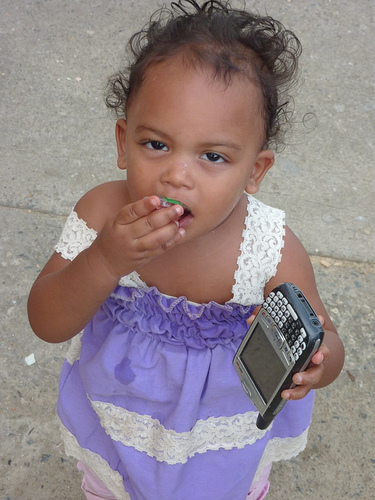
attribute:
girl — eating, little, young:
[23, 1, 349, 500]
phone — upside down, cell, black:
[227, 276, 328, 432]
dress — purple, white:
[48, 187, 320, 496]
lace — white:
[224, 191, 291, 312]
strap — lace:
[48, 200, 149, 299]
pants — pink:
[70, 458, 274, 499]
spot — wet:
[110, 352, 146, 390]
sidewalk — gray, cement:
[3, 2, 372, 500]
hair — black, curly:
[96, 2, 322, 162]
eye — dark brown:
[198, 144, 234, 173]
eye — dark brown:
[131, 131, 177, 163]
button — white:
[284, 301, 300, 324]